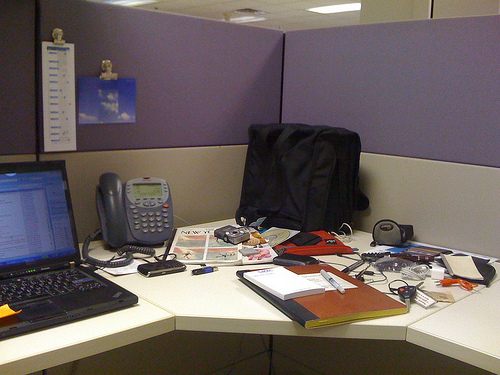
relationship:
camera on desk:
[211, 223, 251, 246] [122, 223, 438, 330]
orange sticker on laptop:
[0, 303, 24, 320] [0, 157, 142, 340]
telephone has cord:
[95, 172, 169, 246] [79, 229, 159, 271]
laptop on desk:
[0, 157, 142, 340] [110, 262, 283, 334]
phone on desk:
[90, 169, 177, 251] [110, 262, 283, 334]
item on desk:
[371, 217, 413, 247] [110, 262, 283, 334]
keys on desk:
[396, 283, 418, 314] [110, 262, 283, 334]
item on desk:
[441, 248, 487, 281] [110, 262, 283, 334]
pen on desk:
[319, 268, 347, 295] [110, 262, 283, 334]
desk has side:
[0, 216, 497, 373] [4, 261, 172, 371]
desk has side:
[0, 216, 497, 373] [174, 209, 420, 343]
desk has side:
[0, 216, 497, 373] [426, 289, 484, 362]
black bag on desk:
[235, 124, 369, 229] [0, 216, 497, 373]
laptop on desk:
[0, 157, 142, 340] [2, 261, 499, 371]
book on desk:
[236, 258, 405, 332] [131, 230, 451, 337]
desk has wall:
[0, 216, 497, 373] [7, 1, 499, 166]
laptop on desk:
[0, 157, 142, 340] [0, 216, 497, 373]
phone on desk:
[95, 175, 175, 241] [0, 216, 497, 373]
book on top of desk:
[233, 261, 411, 332] [191, 261, 498, 338]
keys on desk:
[396, 283, 418, 314] [198, 192, 481, 370]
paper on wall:
[23, 21, 117, 186] [9, 3, 289, 144]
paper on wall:
[76, 61, 137, 123] [1, 6, 498, 153]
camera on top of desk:
[211, 223, 251, 246] [0, 216, 497, 373]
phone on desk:
[90, 169, 177, 251] [0, 216, 500, 375]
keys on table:
[392, 277, 429, 318] [82, 206, 491, 364]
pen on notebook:
[323, 269, 345, 300] [228, 242, 420, 352]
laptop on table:
[0, 157, 142, 340] [4, 171, 494, 358]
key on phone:
[140, 220, 147, 230] [90, 169, 177, 251]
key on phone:
[138, 213, 148, 226] [99, 173, 181, 257]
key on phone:
[128, 215, 144, 230] [78, 161, 207, 244]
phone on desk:
[90, 169, 177, 251] [94, 209, 454, 354]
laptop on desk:
[4, 164, 131, 326] [81, 149, 483, 371]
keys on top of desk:
[396, 283, 418, 314] [191, 270, 252, 321]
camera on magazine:
[213, 224, 248, 246] [164, 206, 246, 286]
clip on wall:
[101, 57, 121, 83] [1, 26, 497, 166]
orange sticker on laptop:
[3, 290, 22, 322] [3, 143, 158, 366]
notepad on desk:
[240, 266, 326, 301] [135, 210, 482, 370]